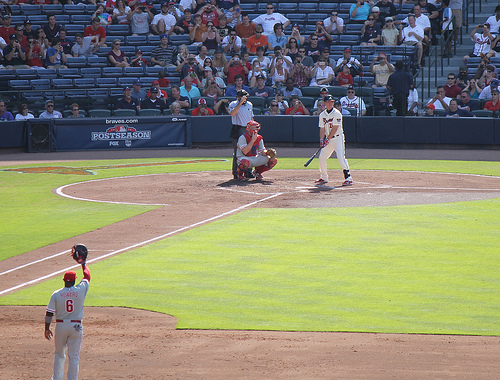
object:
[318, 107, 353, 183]
uniform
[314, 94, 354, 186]
batter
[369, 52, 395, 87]
man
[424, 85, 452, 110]
man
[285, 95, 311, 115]
man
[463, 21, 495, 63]
man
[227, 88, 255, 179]
players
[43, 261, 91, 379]
players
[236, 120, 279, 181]
catcher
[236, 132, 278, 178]
padding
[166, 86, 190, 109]
man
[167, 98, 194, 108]
crossed arms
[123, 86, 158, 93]
hats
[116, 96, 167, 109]
shirts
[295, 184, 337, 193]
home plate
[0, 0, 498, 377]
picture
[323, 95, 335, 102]
hat